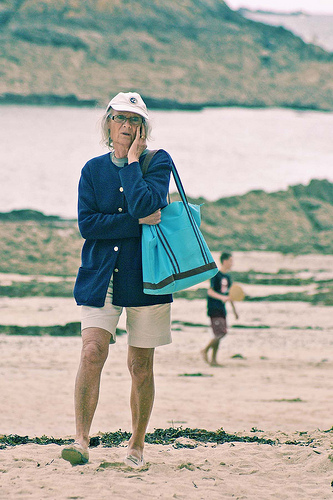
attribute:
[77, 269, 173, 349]
shorts — white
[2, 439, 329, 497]
sand — white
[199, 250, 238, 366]
boy — young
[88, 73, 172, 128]
hat — white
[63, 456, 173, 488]
sand — white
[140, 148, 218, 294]
bag — light blue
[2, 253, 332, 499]
sand — white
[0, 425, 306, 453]
sea weed —  sea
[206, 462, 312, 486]
sand — on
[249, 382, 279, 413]
sand — white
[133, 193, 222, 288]
lines — black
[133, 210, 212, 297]
bag — blue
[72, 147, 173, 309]
sweater — blue